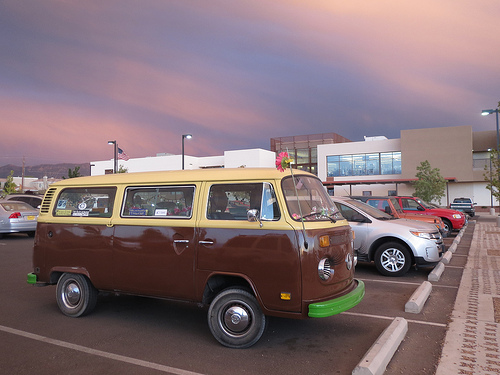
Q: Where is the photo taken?
A: Parking lot.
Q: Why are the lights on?
A: Getting dark.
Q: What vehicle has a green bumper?
A: Van.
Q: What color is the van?
A: Brown.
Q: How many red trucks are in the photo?
A: One.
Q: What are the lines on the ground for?
A: Parking spaces.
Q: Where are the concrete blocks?
A: On ground.